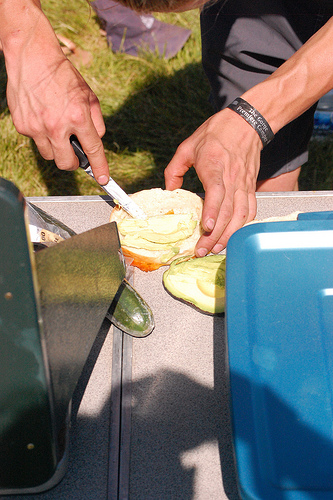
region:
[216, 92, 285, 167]
black and grey bracelet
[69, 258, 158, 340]
green cucumber on table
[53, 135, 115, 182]
man holds black knife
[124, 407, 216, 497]
food on grey table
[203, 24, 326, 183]
man has black shorts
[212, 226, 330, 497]
blue lid on table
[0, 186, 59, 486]
green lid on table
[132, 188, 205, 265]
two slices of bread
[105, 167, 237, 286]
white bread on grey table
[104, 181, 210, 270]
man putting spread on a bun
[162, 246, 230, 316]
a halved avacado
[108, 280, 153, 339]
portion of a cucumber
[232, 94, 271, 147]
black wristband on the person's left wrist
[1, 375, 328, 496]
there is a shadow of an object on the table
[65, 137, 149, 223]
spreading knife in the right hand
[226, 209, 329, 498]
blue lid on top of a bin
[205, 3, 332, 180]
black shorts on the man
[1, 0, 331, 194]
green grass on the ground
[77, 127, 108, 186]
person's right indext finger pointed out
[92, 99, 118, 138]
thumb of a person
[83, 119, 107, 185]
finger of a person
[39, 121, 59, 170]
finger of a person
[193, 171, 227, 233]
finger of a person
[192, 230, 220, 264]
finger of a person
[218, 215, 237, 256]
finger of a person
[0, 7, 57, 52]
a wrist of a person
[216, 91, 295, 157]
a wrist of a person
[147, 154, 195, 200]
a thumb of a person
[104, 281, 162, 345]
Cucumber wrapped in plastic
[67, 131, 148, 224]
Knife spreading condiment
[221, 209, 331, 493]
Blue lid of plastic container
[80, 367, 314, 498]
Shadow going across table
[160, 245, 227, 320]
top of sandwich bun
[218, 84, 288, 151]
black bracelet on left wrist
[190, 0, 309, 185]
Grey leg of shorts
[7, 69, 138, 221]
hand holding knife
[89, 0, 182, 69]
Blue piece of cloth in grass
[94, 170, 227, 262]
bun on the table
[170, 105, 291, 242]
hand of the person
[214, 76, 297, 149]
bracelet around person's wrist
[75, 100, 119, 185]
finger of the person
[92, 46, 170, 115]
grass on the ground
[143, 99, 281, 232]
hand of the person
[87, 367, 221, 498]
shadow on the ground